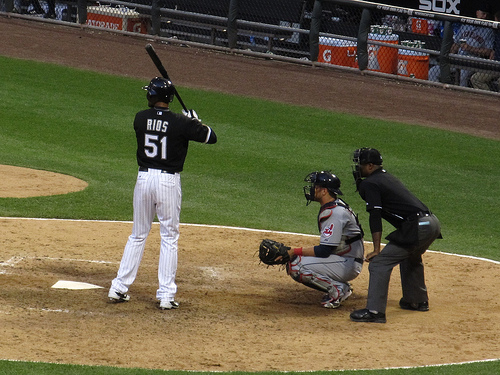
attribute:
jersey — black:
[132, 105, 206, 175]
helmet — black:
[139, 74, 179, 109]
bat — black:
[145, 40, 193, 120]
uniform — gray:
[285, 208, 358, 303]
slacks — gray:
[373, 215, 433, 338]